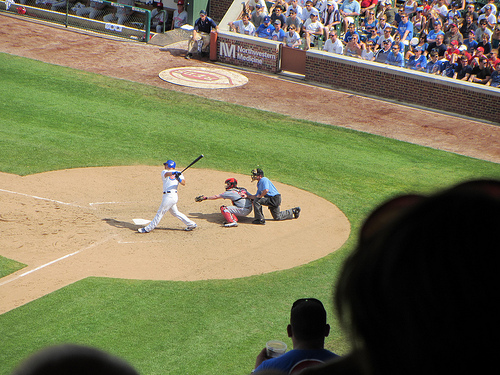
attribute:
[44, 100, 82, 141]
grass — greeny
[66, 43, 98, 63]
field — play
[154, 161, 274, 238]
people — playing, watching, side view, back view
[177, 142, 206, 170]
bat — black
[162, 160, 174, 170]
helmet — blue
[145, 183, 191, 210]
outfit — white, grey, blue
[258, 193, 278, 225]
pants — black, white, grey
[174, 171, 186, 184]
glove — worn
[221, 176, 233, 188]
mask — red, black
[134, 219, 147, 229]
plate — white